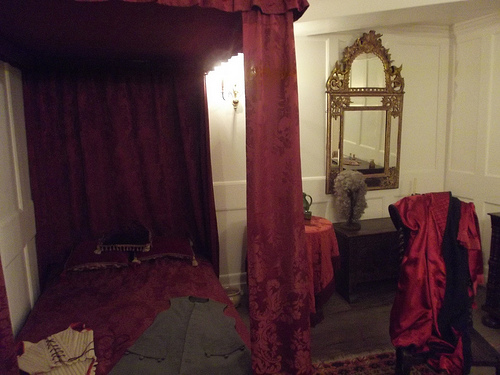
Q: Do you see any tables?
A: Yes, there is a table.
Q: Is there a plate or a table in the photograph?
A: Yes, there is a table.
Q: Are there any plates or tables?
A: Yes, there is a table.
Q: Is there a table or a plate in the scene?
A: Yes, there is a table.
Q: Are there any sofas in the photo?
A: No, there are no sofas.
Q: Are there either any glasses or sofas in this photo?
A: No, there are no sofas or glasses.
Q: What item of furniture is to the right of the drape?
A: The piece of furniture is a table.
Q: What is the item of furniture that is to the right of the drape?
A: The piece of furniture is a table.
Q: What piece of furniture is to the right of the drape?
A: The piece of furniture is a table.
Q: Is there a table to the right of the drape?
A: Yes, there is a table to the right of the drape.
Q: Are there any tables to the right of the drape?
A: Yes, there is a table to the right of the drape.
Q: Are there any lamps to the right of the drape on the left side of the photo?
A: No, there is a table to the right of the drape.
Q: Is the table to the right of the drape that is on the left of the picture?
A: Yes, the table is to the right of the drapery.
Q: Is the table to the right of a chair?
A: No, the table is to the right of the drapery.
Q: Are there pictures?
A: No, there are no pictures.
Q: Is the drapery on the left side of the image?
A: Yes, the drapery is on the left of the image.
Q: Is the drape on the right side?
A: No, the drape is on the left of the image.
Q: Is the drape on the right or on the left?
A: The drape is on the left of the image.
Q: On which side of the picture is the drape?
A: The drape is on the left of the image.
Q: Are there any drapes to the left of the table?
A: Yes, there is a drape to the left of the table.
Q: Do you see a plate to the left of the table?
A: No, there is a drape to the left of the table.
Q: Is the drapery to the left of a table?
A: Yes, the drapery is to the left of a table.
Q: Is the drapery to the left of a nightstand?
A: No, the drapery is to the left of a table.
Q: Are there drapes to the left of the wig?
A: Yes, there is a drape to the left of the wig.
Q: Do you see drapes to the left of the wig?
A: Yes, there is a drape to the left of the wig.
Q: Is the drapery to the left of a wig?
A: Yes, the drapery is to the left of a wig.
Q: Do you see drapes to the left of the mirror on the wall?
A: Yes, there is a drape to the left of the mirror.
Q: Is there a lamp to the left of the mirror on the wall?
A: No, there is a drape to the left of the mirror.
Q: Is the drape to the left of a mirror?
A: Yes, the drape is to the left of a mirror.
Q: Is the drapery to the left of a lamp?
A: No, the drapery is to the left of a mirror.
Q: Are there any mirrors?
A: Yes, there is a mirror.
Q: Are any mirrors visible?
A: Yes, there is a mirror.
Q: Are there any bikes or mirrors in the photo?
A: Yes, there is a mirror.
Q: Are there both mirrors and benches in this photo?
A: No, there is a mirror but no benches.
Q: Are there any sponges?
A: No, there are no sponges.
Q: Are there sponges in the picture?
A: No, there are no sponges.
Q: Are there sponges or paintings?
A: No, there are no sponges or paintings.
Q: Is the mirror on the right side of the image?
A: Yes, the mirror is on the right of the image.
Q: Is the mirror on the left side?
A: No, the mirror is on the right of the image.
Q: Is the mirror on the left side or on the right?
A: The mirror is on the right of the image.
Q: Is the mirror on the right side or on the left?
A: The mirror is on the right of the image.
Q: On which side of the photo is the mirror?
A: The mirror is on the right of the image.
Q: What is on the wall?
A: The mirror is on the wall.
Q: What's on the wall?
A: The mirror is on the wall.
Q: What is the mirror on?
A: The mirror is on the wall.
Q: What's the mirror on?
A: The mirror is on the wall.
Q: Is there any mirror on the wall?
A: Yes, there is a mirror on the wall.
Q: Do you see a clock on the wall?
A: No, there is a mirror on the wall.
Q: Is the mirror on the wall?
A: Yes, the mirror is on the wall.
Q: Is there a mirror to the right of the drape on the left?
A: Yes, there is a mirror to the right of the drape.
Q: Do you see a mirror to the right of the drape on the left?
A: Yes, there is a mirror to the right of the drape.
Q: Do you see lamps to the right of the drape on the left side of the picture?
A: No, there is a mirror to the right of the drapery.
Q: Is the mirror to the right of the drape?
A: Yes, the mirror is to the right of the drape.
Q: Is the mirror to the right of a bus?
A: No, the mirror is to the right of the drape.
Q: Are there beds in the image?
A: Yes, there is a bed.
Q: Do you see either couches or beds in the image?
A: Yes, there is a bed.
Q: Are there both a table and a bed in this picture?
A: Yes, there are both a bed and a table.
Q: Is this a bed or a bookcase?
A: This is a bed.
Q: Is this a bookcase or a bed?
A: This is a bed.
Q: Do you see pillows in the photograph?
A: Yes, there is a pillow.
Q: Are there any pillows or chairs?
A: Yes, there is a pillow.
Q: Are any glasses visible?
A: No, there are no glasses.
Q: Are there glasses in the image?
A: No, there are no glasses.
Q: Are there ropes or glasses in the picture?
A: No, there are no glasses or ropes.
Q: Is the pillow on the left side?
A: Yes, the pillow is on the left of the image.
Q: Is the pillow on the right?
A: No, the pillow is on the left of the image.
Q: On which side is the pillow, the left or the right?
A: The pillow is on the left of the image.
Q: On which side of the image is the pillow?
A: The pillow is on the left of the image.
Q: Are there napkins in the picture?
A: No, there are no napkins.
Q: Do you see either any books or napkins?
A: No, there are no napkins or books.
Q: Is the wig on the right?
A: Yes, the wig is on the right of the image.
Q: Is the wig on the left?
A: No, the wig is on the right of the image.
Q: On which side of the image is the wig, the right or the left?
A: The wig is on the right of the image.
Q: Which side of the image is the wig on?
A: The wig is on the right of the image.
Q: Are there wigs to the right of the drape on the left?
A: Yes, there is a wig to the right of the drapery.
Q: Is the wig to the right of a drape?
A: Yes, the wig is to the right of a drape.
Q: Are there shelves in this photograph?
A: No, there are no shelves.